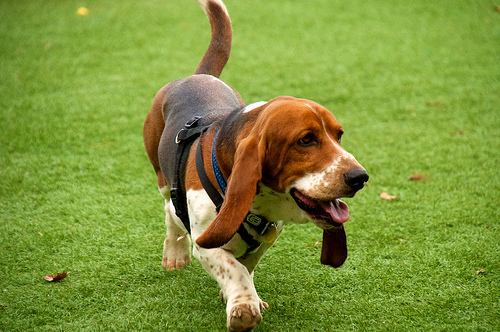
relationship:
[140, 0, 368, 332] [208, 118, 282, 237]
dog wearing collar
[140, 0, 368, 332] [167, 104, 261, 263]
dog wearing harness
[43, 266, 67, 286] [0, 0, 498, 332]
leaf on top of grass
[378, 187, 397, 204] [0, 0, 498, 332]
leaf on top of grass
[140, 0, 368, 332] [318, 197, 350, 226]
dog has tongue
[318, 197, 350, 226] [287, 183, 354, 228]
tongue sticking out of mouth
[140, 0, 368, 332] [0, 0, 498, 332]
dog running on grass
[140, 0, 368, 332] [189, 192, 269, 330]
dog has front leg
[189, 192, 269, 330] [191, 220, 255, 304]
front leg has speckles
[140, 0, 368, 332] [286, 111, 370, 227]
dog has face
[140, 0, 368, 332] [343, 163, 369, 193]
dog has nose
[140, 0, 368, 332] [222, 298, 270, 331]
dog has front paw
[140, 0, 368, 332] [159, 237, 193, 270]
dog has back paw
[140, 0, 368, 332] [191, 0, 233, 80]
dog has tail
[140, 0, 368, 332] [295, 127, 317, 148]
dog has right eye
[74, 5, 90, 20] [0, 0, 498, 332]
ball on top of grass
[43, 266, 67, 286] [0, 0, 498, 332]
leaf laying on grass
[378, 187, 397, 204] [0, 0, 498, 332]
leaf laying on grass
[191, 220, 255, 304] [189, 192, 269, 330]
speckles on front leg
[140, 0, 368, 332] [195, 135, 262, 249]
dog has ear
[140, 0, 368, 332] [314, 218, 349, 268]
dog has ear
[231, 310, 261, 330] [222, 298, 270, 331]
pads on bottom of front paw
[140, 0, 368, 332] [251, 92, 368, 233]
dog has head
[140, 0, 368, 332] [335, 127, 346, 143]
dog has left eye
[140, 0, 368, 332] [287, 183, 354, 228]
dog has mouth